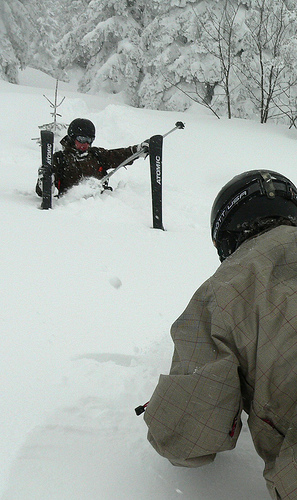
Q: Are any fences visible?
A: No, there are no fences.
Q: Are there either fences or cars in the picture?
A: No, there are no fences or cars.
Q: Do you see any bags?
A: No, there are no bags.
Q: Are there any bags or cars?
A: No, there are no bags or cars.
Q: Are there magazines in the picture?
A: No, there are no magazines.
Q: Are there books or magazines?
A: No, there are no magazines or books.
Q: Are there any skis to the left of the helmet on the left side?
A: Yes, there is a ski to the left of the helmet.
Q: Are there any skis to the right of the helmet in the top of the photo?
A: No, the ski is to the left of the helmet.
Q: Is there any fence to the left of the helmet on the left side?
A: No, there is a ski to the left of the helmet.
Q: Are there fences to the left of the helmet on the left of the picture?
A: No, there is a ski to the left of the helmet.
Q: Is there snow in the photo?
A: Yes, there is snow.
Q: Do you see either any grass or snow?
A: Yes, there is snow.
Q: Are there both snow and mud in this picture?
A: No, there is snow but no mud.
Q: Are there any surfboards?
A: No, there are no surfboards.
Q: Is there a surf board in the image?
A: No, there are no surfboards.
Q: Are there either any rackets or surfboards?
A: No, there are no surfboards or rackets.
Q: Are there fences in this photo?
A: No, there are no fences.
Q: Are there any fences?
A: No, there are no fences.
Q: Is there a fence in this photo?
A: No, there are no fences.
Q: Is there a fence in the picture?
A: No, there are no fences.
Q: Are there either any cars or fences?
A: No, there are no fences or cars.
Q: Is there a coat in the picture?
A: Yes, there is a coat.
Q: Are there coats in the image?
A: Yes, there is a coat.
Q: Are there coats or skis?
A: Yes, there is a coat.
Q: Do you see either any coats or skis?
A: Yes, there is a coat.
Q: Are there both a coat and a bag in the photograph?
A: No, there is a coat but no bags.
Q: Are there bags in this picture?
A: No, there are no bags.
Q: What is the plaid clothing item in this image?
A: The clothing item is a coat.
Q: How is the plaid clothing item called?
A: The clothing item is a coat.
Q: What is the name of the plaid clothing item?
A: The clothing item is a coat.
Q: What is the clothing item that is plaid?
A: The clothing item is a coat.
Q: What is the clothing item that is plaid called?
A: The clothing item is a coat.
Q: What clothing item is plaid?
A: The clothing item is a coat.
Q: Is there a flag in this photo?
A: No, there are no flags.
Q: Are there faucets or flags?
A: No, there are no flags or faucets.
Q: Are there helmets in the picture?
A: Yes, there is a helmet.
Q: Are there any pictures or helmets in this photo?
A: Yes, there is a helmet.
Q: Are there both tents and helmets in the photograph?
A: No, there is a helmet but no tents.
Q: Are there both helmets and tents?
A: No, there is a helmet but no tents.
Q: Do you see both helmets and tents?
A: No, there is a helmet but no tents.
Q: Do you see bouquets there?
A: No, there are no bouquets.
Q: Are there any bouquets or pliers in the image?
A: No, there are no bouquets or pliers.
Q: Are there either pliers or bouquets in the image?
A: No, there are no bouquets or pliers.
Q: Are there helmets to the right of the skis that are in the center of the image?
A: Yes, there is a helmet to the right of the skis.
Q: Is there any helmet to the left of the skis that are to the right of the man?
A: No, the helmet is to the right of the skis.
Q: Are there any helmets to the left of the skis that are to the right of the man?
A: No, the helmet is to the right of the skis.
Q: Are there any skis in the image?
A: Yes, there are skis.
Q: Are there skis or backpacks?
A: Yes, there are skis.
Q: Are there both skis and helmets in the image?
A: Yes, there are both skis and a helmet.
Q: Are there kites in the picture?
A: No, there are no kites.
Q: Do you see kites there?
A: No, there are no kites.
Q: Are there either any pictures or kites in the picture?
A: No, there are no kites or pictures.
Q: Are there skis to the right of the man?
A: Yes, there are skis to the right of the man.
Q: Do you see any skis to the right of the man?
A: Yes, there are skis to the right of the man.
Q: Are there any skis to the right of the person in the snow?
A: Yes, there are skis to the right of the man.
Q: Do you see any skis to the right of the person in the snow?
A: Yes, there are skis to the right of the man.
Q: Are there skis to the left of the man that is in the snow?
A: No, the skis are to the right of the man.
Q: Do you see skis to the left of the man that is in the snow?
A: No, the skis are to the right of the man.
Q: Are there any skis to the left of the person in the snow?
A: No, the skis are to the right of the man.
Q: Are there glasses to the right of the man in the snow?
A: No, there are skis to the right of the man.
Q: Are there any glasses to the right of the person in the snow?
A: No, there are skis to the right of the man.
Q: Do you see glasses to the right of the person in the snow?
A: No, there are skis to the right of the man.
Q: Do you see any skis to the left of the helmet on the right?
A: Yes, there are skis to the left of the helmet.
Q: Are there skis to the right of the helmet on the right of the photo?
A: No, the skis are to the left of the helmet.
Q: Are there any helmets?
A: Yes, there is a helmet.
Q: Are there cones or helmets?
A: Yes, there is a helmet.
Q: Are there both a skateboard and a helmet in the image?
A: No, there is a helmet but no skateboards.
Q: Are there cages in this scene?
A: No, there are no cages.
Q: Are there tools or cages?
A: No, there are no cages or tools.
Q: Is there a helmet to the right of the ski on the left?
A: Yes, there is a helmet to the right of the ski.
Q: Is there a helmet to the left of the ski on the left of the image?
A: No, the helmet is to the right of the ski.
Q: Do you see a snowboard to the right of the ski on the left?
A: No, there is a helmet to the right of the ski.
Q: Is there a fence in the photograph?
A: No, there are no fences.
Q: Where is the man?
A: The man is in the snow.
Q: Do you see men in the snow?
A: Yes, there is a man in the snow.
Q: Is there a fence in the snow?
A: No, there is a man in the snow.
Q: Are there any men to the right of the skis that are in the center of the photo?
A: No, the man is to the left of the skis.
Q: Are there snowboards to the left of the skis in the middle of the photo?
A: No, there is a man to the left of the skis.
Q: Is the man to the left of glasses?
A: No, the man is to the left of the skis.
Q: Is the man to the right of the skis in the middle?
A: No, the man is to the left of the skis.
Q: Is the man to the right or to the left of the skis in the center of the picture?
A: The man is to the left of the skis.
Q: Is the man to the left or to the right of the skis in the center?
A: The man is to the left of the skis.